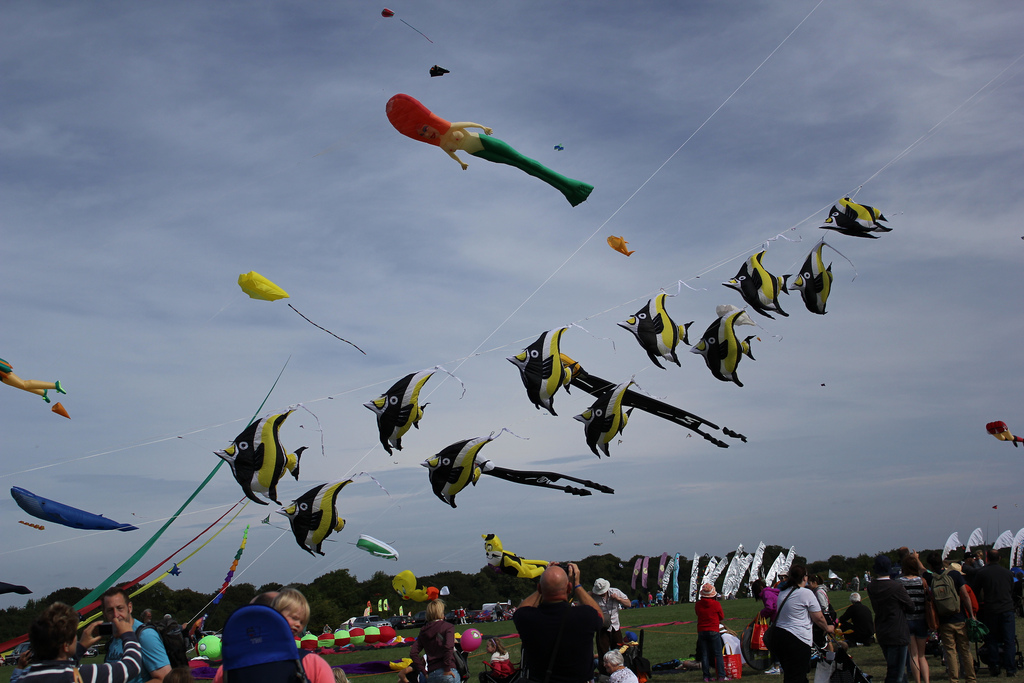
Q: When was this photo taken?
A: In the daytime.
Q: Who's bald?
A: One of the guys.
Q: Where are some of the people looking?
A: Up.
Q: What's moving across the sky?
A: Kites.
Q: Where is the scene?
A: At a kite festival.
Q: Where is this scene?
A: At a kite festival.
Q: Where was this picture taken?
A: Kite festival.